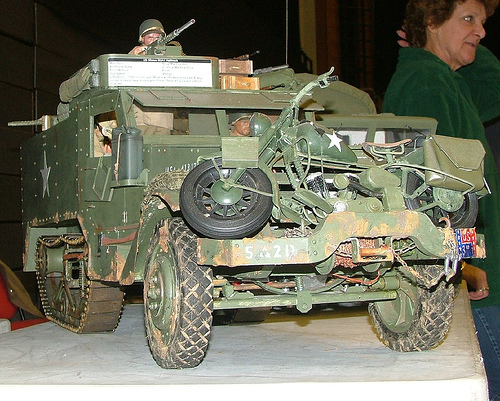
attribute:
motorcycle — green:
[175, 64, 483, 241]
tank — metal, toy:
[14, 42, 481, 369]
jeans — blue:
[481, 312, 496, 347]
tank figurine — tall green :
[9, 17, 491, 369]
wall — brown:
[0, 0, 311, 267]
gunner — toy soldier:
[120, 14, 221, 61]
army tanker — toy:
[6, 17, 490, 370]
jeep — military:
[18, 22, 490, 369]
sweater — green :
[381, 49, 497, 151]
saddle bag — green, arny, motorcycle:
[417, 126, 494, 195]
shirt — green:
[383, 45, 480, 147]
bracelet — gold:
[450, 254, 469, 284]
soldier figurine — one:
[129, 18, 183, 55]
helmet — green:
[139, 18, 166, 40]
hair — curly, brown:
[406, 0, 499, 64]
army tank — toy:
[8, 16, 490, 372]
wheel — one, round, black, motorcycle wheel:
[176, 151, 273, 240]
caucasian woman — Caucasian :
[411, 2, 493, 89]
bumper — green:
[190, 207, 491, 268]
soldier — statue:
[96, 17, 208, 60]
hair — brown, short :
[399, 1, 490, 48]